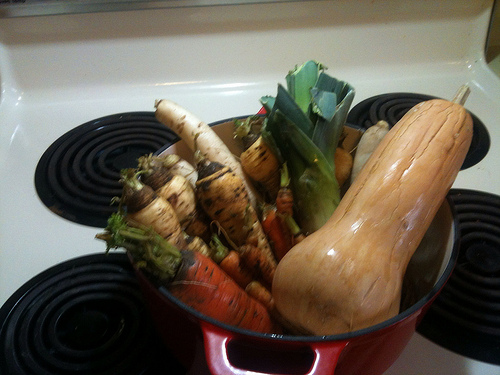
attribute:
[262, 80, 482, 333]
squash — long 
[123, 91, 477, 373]
pot — red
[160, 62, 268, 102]
reflection — light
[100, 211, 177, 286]
top — green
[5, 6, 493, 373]
oven — white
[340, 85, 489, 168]
burner — electric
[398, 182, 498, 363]
burner — electric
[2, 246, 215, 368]
burner — electric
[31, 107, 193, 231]
burner — electric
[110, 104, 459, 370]
bowl — shiny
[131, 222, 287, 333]
carrot — orange, tan , dirty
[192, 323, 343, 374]
handle — red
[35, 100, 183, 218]
grill — black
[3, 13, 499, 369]
stove — white, indoors, inside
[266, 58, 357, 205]
leaves — green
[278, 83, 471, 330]
vegetable — tan, green